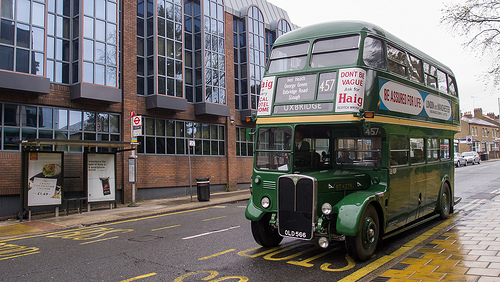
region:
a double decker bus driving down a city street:
[204, 14, 469, 266]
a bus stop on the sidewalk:
[11, 136, 139, 220]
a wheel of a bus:
[344, 202, 381, 262]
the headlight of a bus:
[259, 195, 272, 212]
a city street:
[25, 229, 222, 277]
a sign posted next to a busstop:
[129, 110, 146, 211]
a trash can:
[197, 174, 210, 205]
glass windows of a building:
[81, 10, 116, 78]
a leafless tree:
[440, 3, 498, 65]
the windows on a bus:
[391, 137, 449, 162]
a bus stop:
[14, 118, 159, 225]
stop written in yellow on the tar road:
[50, 215, 415, 280]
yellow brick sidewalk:
[383, 167, 496, 280]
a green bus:
[215, 11, 467, 266]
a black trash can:
[184, 162, 236, 215]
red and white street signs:
[121, 85, 174, 209]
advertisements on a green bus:
[256, 55, 476, 132]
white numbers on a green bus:
[247, 168, 407, 244]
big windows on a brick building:
[1, 0, 345, 185]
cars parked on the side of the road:
[408, 132, 486, 172]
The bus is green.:
[258, 29, 443, 251]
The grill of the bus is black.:
[270, 165, 319, 242]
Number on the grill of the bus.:
[273, 218, 311, 250]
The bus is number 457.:
[307, 70, 338, 101]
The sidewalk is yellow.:
[418, 226, 498, 279]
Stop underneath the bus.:
[237, 216, 361, 280]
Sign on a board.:
[9, 140, 74, 219]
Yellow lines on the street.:
[133, 242, 247, 272]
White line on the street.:
[175, 212, 255, 256]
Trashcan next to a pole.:
[173, 173, 225, 206]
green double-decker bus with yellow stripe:
[187, 15, 482, 260]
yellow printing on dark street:
[5, 205, 345, 280]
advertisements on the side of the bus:
[370, 70, 450, 125]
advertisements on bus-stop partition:
[20, 125, 125, 230]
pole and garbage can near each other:
[171, 117, 226, 214]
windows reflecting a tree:
[71, 15, 132, 90]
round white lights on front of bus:
[241, 185, 341, 251]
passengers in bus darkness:
[261, 127, 371, 167]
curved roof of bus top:
[260, 11, 457, 81]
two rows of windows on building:
[143, 115, 220, 162]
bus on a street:
[236, 10, 475, 269]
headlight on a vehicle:
[255, 190, 275, 214]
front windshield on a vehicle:
[246, 119, 301, 177]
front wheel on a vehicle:
[337, 191, 389, 267]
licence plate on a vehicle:
[278, 225, 312, 242]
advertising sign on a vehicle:
[371, 71, 457, 128]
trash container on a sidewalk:
[191, 170, 216, 212]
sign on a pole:
[126, 108, 148, 143]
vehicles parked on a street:
[451, 143, 488, 171]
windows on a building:
[3, 96, 131, 153]